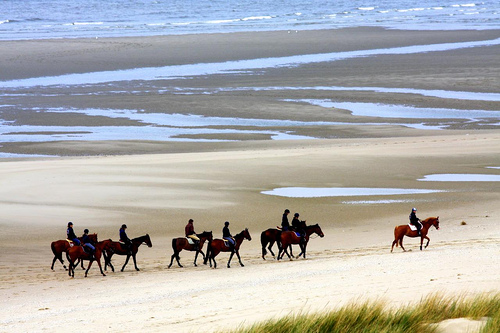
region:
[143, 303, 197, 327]
this is the ground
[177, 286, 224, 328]
the ground is sandy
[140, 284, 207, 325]
the sand is brown in color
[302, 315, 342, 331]
this is the grass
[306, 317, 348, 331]
the grass is tall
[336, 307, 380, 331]
the grass is green in color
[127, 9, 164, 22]
this is the water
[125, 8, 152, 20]
the water is blue in color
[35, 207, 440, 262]
people riding some horses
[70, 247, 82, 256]
the fur is brown in color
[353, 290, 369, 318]
part of a grass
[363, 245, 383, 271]
part f a dads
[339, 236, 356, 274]
part of a loine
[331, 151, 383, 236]
part f a ponf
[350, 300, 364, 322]
part of a grass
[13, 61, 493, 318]
horses on a beach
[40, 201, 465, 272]
eight horse riders on the beach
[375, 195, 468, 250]
this is the lead horse rider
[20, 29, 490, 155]
the coast has a lot of water and sand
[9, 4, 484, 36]
hte ocean in the background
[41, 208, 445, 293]
all of these horses are brown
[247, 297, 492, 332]
grass along the beach area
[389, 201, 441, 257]
this horse rider has a white covering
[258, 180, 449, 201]
a pool of water along the beach area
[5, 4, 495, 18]
waves in the water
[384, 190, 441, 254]
a person riding a horse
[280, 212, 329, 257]
a person riding a horse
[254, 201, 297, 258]
a person riding a horse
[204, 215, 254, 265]
a person riding a horse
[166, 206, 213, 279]
a person riding a horse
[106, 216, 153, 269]
a person riding a horse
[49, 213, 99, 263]
a person riding a horse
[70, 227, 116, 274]
a person riding a horse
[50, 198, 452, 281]
people on horses in a line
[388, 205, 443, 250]
person in front of the line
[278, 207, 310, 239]
people riding horses on sand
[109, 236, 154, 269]
horse walking on sand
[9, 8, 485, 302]
beach with sand and water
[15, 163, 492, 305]
sand region of beach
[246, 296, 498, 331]
grass on the beach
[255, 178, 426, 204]
pools of water in sand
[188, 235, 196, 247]
covering over horse's body